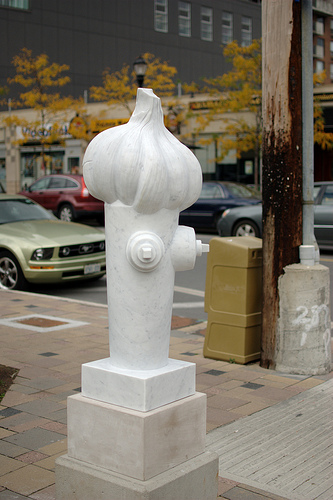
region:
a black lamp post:
[130, 55, 148, 87]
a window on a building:
[199, 4, 214, 44]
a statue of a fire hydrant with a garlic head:
[84, 81, 211, 411]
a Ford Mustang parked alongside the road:
[0, 192, 107, 292]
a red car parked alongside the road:
[18, 170, 105, 223]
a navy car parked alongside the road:
[170, 176, 258, 229]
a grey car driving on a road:
[216, 178, 331, 256]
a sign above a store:
[15, 121, 78, 143]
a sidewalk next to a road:
[1, 289, 331, 498]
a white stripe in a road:
[173, 283, 209, 297]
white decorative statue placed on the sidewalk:
[74, 76, 202, 499]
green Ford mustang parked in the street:
[1, 190, 108, 299]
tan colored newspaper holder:
[204, 228, 266, 365]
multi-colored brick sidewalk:
[4, 291, 82, 400]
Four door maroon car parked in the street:
[15, 174, 103, 223]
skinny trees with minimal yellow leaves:
[5, 41, 330, 172]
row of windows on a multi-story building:
[153, 0, 254, 54]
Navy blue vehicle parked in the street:
[182, 178, 256, 238]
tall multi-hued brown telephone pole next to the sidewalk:
[262, 1, 322, 364]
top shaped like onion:
[83, 98, 199, 215]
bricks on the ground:
[0, 427, 41, 474]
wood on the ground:
[244, 438, 317, 467]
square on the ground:
[4, 311, 73, 335]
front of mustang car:
[40, 239, 98, 257]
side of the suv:
[26, 176, 88, 219]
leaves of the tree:
[206, 73, 259, 96]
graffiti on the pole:
[283, 295, 323, 343]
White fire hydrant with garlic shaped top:
[55, 87, 218, 498]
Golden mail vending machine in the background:
[200, 234, 264, 365]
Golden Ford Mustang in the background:
[0, 194, 106, 299]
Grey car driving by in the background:
[216, 175, 331, 247]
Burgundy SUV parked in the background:
[17, 170, 107, 223]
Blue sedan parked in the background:
[178, 181, 261, 229]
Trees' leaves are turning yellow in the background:
[0, 34, 332, 177]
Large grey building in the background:
[0, 0, 260, 111]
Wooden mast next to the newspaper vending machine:
[261, 0, 301, 366]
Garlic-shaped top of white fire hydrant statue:
[82, 88, 202, 211]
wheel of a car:
[0, 250, 24, 289]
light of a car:
[22, 225, 57, 266]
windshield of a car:
[5, 190, 56, 224]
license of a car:
[74, 258, 103, 278]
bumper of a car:
[26, 221, 107, 292]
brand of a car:
[77, 242, 90, 256]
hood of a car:
[9, 217, 98, 256]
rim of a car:
[0, 255, 18, 289]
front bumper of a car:
[22, 260, 109, 285]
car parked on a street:
[26, 161, 102, 238]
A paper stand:
[202, 235, 259, 368]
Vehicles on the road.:
[3, 166, 332, 331]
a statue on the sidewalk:
[77, 85, 225, 494]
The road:
[1, 202, 332, 329]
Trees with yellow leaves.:
[5, 40, 331, 173]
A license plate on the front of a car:
[85, 262, 100, 273]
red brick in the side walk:
[0, 462, 52, 497]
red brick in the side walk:
[35, 435, 70, 453]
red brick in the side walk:
[13, 448, 46, 462]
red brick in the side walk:
[37, 417, 65, 429]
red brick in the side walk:
[204, 390, 248, 409]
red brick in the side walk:
[251, 383, 295, 399]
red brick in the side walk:
[194, 370, 230, 382]